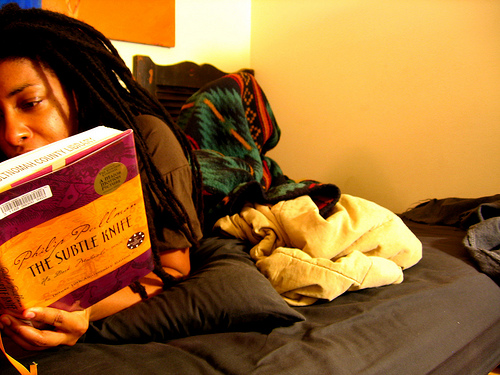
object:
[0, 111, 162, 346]
book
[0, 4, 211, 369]
girl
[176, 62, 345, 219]
blanket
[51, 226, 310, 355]
pillow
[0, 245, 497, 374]
bed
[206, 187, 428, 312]
white blanket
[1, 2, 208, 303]
hair style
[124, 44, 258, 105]
door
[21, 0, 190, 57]
painting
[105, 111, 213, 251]
brown t-shirt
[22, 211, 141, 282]
"the subtle knife"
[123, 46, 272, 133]
chair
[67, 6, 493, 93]
background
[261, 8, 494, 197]
wall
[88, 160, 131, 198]
sticker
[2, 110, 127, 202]
edge of book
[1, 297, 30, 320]
nails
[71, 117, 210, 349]
arm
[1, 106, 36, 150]
nose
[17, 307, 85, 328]
fingers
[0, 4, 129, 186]
girl head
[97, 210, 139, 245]
knife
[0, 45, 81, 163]
face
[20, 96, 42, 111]
eyeball